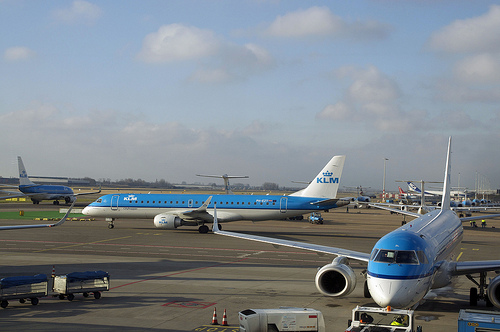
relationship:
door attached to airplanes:
[111, 191, 121, 210] [80, 155, 352, 232]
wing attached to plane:
[204, 204, 366, 262] [209, 137, 499, 314]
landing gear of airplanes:
[106, 221, 114, 229] [80, 155, 352, 232]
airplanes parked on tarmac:
[80, 152, 352, 232] [30, 190, 474, 324]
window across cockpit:
[368, 244, 427, 267] [361, 233, 431, 282]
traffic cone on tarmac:
[220, 306, 228, 324] [91, 212, 329, 306]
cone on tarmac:
[209, 306, 217, 324] [91, 212, 329, 306]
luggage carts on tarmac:
[10, 260, 123, 308] [10, 202, 463, 330]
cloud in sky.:
[137, 18, 227, 53] [228, 33, 404, 124]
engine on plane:
[313, 265, 355, 300] [209, 137, 499, 314]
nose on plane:
[361, 269, 431, 317] [209, 137, 499, 314]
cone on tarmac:
[206, 303, 222, 327] [13, 236, 383, 331]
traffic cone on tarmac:
[220, 306, 228, 324] [13, 236, 383, 331]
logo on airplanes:
[316, 169, 338, 183] [80, 155, 352, 232]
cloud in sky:
[148, 22, 215, 63] [90, 43, 287, 180]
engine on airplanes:
[152, 212, 188, 228] [80, 155, 352, 232]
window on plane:
[367, 245, 431, 267] [209, 137, 499, 314]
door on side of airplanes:
[277, 194, 287, 211] [80, 155, 352, 232]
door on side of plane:
[111, 191, 121, 210] [45, 132, 424, 279]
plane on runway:
[0, 153, 103, 202] [0, 185, 175, 224]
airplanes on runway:
[80, 155, 352, 232] [0, 185, 175, 224]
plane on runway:
[209, 137, 499, 314] [0, 185, 175, 224]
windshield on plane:
[368, 250, 415, 265] [209, 137, 499, 314]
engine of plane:
[313, 265, 353, 295] [209, 137, 499, 314]